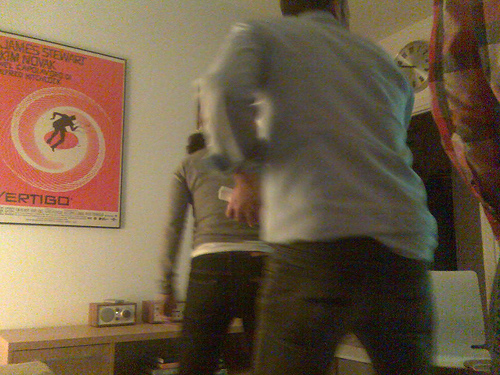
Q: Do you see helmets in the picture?
A: No, there are no helmets.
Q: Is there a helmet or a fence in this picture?
A: No, there are no helmets or fences.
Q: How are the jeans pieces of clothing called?
A: The clothing items are pants.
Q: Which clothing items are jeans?
A: The clothing items are pants.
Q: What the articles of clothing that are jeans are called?
A: The clothing items are pants.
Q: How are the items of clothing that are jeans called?
A: The clothing items are pants.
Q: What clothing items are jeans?
A: The clothing items are pants.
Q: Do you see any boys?
A: No, there are no boys.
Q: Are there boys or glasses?
A: No, there are no boys or glasses.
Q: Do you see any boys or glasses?
A: No, there are no boys or glasses.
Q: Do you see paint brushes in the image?
A: No, there are no paint brushes.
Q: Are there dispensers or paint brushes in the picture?
A: No, there are no paint brushes or dispensers.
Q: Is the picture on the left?
A: Yes, the picture is on the left of the image.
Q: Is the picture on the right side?
A: No, the picture is on the left of the image.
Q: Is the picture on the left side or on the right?
A: The picture is on the left of the image.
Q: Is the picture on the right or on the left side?
A: The picture is on the left of the image.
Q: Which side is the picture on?
A: The picture is on the left of the image.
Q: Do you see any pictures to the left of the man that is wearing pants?
A: Yes, there is a picture to the left of the man.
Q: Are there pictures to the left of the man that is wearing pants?
A: Yes, there is a picture to the left of the man.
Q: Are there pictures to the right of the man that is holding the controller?
A: No, the picture is to the left of the man.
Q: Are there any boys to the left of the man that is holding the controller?
A: No, there is a picture to the left of the man.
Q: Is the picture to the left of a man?
A: Yes, the picture is to the left of a man.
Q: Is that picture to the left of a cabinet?
A: No, the picture is to the left of a man.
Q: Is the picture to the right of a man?
A: No, the picture is to the left of a man.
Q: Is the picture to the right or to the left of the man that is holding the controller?
A: The picture is to the left of the man.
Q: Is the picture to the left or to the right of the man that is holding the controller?
A: The picture is to the left of the man.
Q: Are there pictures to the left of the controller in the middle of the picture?
A: Yes, there is a picture to the left of the controller.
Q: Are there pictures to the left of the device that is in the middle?
A: Yes, there is a picture to the left of the controller.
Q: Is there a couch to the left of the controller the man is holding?
A: No, there is a picture to the left of the controller.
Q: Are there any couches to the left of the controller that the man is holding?
A: No, there is a picture to the left of the controller.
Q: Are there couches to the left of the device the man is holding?
A: No, there is a picture to the left of the controller.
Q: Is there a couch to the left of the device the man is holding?
A: No, there is a picture to the left of the controller.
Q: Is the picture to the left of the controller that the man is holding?
A: Yes, the picture is to the left of the controller.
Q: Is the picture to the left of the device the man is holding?
A: Yes, the picture is to the left of the controller.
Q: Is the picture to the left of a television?
A: No, the picture is to the left of the controller.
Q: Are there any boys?
A: No, there are no boys.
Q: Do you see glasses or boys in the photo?
A: No, there are no boys or glasses.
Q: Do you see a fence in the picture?
A: No, there are no fences.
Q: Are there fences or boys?
A: No, there are no fences or boys.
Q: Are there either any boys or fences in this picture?
A: No, there are no fences or boys.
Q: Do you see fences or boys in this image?
A: No, there are no fences or boys.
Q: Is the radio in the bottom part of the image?
A: Yes, the radio is in the bottom of the image.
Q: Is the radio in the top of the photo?
A: No, the radio is in the bottom of the image.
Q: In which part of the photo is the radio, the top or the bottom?
A: The radio is in the bottom of the image.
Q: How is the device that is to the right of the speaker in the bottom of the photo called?
A: The device is a radio.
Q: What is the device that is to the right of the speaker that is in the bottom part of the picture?
A: The device is a radio.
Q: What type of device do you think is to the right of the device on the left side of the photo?
A: The device is a radio.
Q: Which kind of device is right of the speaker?
A: The device is a radio.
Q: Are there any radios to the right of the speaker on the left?
A: Yes, there is a radio to the right of the speaker.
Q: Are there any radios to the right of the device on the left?
A: Yes, there is a radio to the right of the speaker.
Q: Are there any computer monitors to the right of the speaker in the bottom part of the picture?
A: No, there is a radio to the right of the speaker.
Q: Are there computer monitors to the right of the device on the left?
A: No, there is a radio to the right of the speaker.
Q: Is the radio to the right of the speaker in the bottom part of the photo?
A: Yes, the radio is to the right of the speaker.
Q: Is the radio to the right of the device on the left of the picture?
A: Yes, the radio is to the right of the speaker.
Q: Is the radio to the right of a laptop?
A: No, the radio is to the right of the speaker.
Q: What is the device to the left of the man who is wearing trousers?
A: The device is a radio.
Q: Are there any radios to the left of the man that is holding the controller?
A: Yes, there is a radio to the left of the man.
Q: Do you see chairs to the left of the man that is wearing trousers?
A: No, there is a radio to the left of the man.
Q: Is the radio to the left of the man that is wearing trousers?
A: Yes, the radio is to the left of the man.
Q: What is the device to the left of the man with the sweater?
A: The device is a radio.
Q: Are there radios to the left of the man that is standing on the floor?
A: Yes, there is a radio to the left of the man.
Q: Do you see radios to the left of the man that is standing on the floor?
A: Yes, there is a radio to the left of the man.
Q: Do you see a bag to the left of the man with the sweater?
A: No, there is a radio to the left of the man.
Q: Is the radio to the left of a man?
A: Yes, the radio is to the left of a man.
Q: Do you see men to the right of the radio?
A: Yes, there is a man to the right of the radio.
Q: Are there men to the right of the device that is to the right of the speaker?
A: Yes, there is a man to the right of the radio.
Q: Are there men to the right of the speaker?
A: Yes, there is a man to the right of the speaker.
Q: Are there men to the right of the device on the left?
A: Yes, there is a man to the right of the speaker.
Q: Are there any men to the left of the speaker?
A: No, the man is to the right of the speaker.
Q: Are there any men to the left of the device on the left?
A: No, the man is to the right of the speaker.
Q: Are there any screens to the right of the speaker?
A: No, there is a man to the right of the speaker.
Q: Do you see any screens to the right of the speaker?
A: No, there is a man to the right of the speaker.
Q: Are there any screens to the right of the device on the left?
A: No, there is a man to the right of the speaker.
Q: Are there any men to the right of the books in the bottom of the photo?
A: Yes, there is a man to the right of the books.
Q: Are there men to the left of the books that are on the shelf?
A: No, the man is to the right of the books.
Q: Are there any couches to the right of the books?
A: No, there is a man to the right of the books.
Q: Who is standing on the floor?
A: The man is standing on the floor.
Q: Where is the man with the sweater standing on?
A: The man is standing on the floor.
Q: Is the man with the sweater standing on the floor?
A: Yes, the man is standing on the floor.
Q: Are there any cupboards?
A: No, there are no cupboards.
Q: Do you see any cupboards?
A: No, there are no cupboards.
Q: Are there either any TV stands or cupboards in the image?
A: No, there are no cupboards or TV stands.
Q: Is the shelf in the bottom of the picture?
A: Yes, the shelf is in the bottom of the image.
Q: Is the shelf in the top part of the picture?
A: No, the shelf is in the bottom of the image.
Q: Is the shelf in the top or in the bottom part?
A: The shelf is in the bottom of the image.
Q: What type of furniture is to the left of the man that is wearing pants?
A: The piece of furniture is a shelf.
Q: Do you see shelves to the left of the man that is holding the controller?
A: Yes, there is a shelf to the left of the man.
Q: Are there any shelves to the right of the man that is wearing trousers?
A: No, the shelf is to the left of the man.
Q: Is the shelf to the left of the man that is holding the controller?
A: Yes, the shelf is to the left of the man.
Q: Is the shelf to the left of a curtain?
A: No, the shelf is to the left of the man.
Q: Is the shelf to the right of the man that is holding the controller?
A: No, the shelf is to the left of the man.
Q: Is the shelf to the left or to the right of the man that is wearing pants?
A: The shelf is to the left of the man.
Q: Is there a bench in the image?
A: No, there are no benches.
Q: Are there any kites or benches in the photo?
A: No, there are no benches or kites.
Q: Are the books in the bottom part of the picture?
A: Yes, the books are in the bottom of the image.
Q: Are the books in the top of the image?
A: No, the books are in the bottom of the image.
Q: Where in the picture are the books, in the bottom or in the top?
A: The books are in the bottom of the image.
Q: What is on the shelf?
A: The books are on the shelf.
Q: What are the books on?
A: The books are on the shelf.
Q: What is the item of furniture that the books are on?
A: The piece of furniture is a shelf.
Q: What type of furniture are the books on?
A: The books are on the shelf.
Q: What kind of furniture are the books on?
A: The books are on the shelf.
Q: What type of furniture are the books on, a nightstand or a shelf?
A: The books are on a shelf.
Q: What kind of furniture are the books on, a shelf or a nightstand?
A: The books are on a shelf.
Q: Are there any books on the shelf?
A: Yes, there are books on the shelf.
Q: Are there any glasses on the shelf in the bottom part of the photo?
A: No, there are books on the shelf.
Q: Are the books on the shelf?
A: Yes, the books are on the shelf.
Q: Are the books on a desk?
A: No, the books are on the shelf.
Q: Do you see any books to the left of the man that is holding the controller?
A: Yes, there are books to the left of the man.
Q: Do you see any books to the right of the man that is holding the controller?
A: No, the books are to the left of the man.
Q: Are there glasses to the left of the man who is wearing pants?
A: No, there are books to the left of the man.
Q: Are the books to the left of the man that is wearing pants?
A: Yes, the books are to the left of the man.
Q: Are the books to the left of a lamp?
A: No, the books are to the left of the man.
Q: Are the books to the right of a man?
A: No, the books are to the left of a man.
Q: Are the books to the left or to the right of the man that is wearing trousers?
A: The books are to the left of the man.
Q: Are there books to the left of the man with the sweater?
A: Yes, there are books to the left of the man.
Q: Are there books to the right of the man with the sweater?
A: No, the books are to the left of the man.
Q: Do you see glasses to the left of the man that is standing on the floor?
A: No, there are books to the left of the man.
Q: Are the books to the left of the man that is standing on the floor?
A: Yes, the books are to the left of the man.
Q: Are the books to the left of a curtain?
A: No, the books are to the left of the man.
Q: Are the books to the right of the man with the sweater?
A: No, the books are to the left of the man.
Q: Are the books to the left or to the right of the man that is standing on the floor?
A: The books are to the left of the man.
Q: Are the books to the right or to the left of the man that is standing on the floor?
A: The books are to the left of the man.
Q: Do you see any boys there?
A: No, there are no boys.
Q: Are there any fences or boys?
A: No, there are no boys or fences.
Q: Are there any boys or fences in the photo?
A: No, there are no boys or fences.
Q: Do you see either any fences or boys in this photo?
A: No, there are no boys or fences.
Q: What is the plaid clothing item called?
A: The clothing item is a shirt.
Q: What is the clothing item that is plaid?
A: The clothing item is a shirt.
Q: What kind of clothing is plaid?
A: The clothing is a shirt.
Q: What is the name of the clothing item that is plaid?
A: The clothing item is a shirt.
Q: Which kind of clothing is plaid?
A: The clothing is a shirt.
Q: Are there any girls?
A: No, there are no girls.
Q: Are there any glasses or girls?
A: No, there are no girls or glasses.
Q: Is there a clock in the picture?
A: Yes, there is a clock.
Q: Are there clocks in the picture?
A: Yes, there is a clock.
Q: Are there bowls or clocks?
A: Yes, there is a clock.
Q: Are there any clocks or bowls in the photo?
A: Yes, there is a clock.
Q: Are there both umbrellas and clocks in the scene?
A: No, there is a clock but no umbrellas.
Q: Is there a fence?
A: No, there are no fences.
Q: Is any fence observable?
A: No, there are no fences.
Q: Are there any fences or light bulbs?
A: No, there are no fences or light bulbs.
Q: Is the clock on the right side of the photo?
A: Yes, the clock is on the right of the image.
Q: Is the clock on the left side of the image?
A: No, the clock is on the right of the image.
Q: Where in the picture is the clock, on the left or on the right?
A: The clock is on the right of the image.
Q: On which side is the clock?
A: The clock is on the right of the image.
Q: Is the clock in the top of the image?
A: Yes, the clock is in the top of the image.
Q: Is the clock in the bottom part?
A: No, the clock is in the top of the image.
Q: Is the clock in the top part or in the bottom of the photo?
A: The clock is in the top of the image.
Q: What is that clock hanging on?
A: The clock is hanging on the wall.